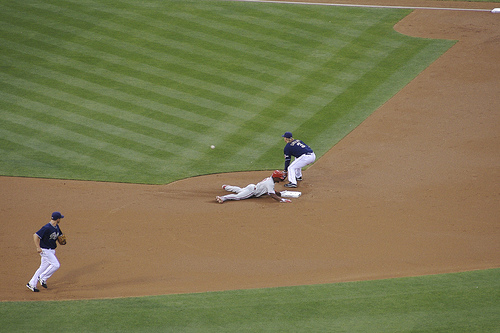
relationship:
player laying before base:
[212, 166, 292, 206] [279, 186, 303, 199]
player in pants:
[25, 210, 65, 292] [27, 248, 58, 295]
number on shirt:
[294, 138, 306, 149] [286, 141, 312, 157]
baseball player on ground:
[212, 165, 296, 208] [0, 0, 499, 332]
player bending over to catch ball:
[280, 130, 317, 187] [210, 143, 215, 148]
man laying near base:
[214, 170, 291, 204] [280, 186, 301, 202]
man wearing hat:
[20, 207, 70, 294] [52, 211, 64, 219]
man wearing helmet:
[214, 170, 291, 204] [267, 169, 284, 181]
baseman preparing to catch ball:
[280, 130, 317, 188] [208, 143, 217, 148]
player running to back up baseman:
[25, 210, 65, 292] [283, 130, 315, 187]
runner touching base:
[214, 168, 294, 208] [277, 179, 304, 201]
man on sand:
[269, 127, 326, 198] [334, 165, 423, 217]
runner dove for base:
[214, 168, 294, 208] [490, 2, 499, 13]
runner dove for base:
[214, 168, 294, 208] [278, 187, 303, 200]